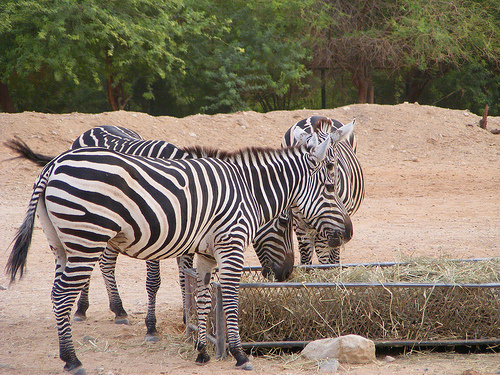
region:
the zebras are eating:
[46, 67, 420, 374]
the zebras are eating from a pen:
[31, 72, 408, 371]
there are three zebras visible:
[11, 58, 397, 364]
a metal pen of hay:
[186, 253, 496, 373]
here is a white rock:
[289, 323, 391, 370]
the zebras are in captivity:
[8, 86, 420, 359]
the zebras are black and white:
[26, 109, 440, 374]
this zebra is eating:
[241, 132, 326, 294]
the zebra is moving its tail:
[3, 115, 108, 178]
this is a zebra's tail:
[5, 144, 53, 294]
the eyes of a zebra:
[290, 157, 372, 212]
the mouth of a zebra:
[300, 196, 370, 266]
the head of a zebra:
[265, 116, 390, 266]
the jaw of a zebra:
[267, 185, 322, 265]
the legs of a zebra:
[165, 235, 286, 363]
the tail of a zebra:
[1, 168, 64, 287]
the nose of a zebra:
[307, 206, 373, 261]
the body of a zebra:
[20, 144, 312, 318]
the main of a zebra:
[189, 125, 312, 187]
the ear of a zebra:
[277, 130, 337, 216]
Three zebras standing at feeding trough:
[2, 114, 367, 374]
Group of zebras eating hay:
[2, 113, 368, 374]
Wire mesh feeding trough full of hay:
[181, 253, 498, 363]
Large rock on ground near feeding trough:
[300, 331, 376, 366]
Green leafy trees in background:
[1, 0, 498, 119]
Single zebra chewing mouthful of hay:
[3, 136, 358, 373]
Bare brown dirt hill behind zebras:
[2, 99, 499, 200]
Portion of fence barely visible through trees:
[306, 63, 345, 109]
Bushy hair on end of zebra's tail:
[5, 222, 34, 287]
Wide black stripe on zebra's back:
[96, 123, 138, 142]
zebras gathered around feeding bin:
[9, 97, 488, 362]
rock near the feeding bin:
[283, 330, 393, 365]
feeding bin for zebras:
[210, 258, 499, 351]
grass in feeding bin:
[254, 270, 494, 338]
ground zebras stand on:
[6, 117, 498, 364]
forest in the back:
[5, 7, 492, 115]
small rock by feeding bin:
[385, 353, 399, 368]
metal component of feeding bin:
[346, 273, 409, 293]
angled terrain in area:
[358, 101, 498, 186]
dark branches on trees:
[331, 34, 390, 71]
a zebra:
[49, 145, 384, 244]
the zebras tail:
[14, 217, 43, 264]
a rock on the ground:
[302, 336, 379, 367]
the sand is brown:
[396, 178, 473, 231]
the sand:
[390, 189, 456, 240]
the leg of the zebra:
[217, 286, 252, 367]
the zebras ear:
[306, 131, 332, 156]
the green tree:
[92, 15, 243, 82]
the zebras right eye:
[325, 179, 338, 196]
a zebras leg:
[137, 276, 167, 339]